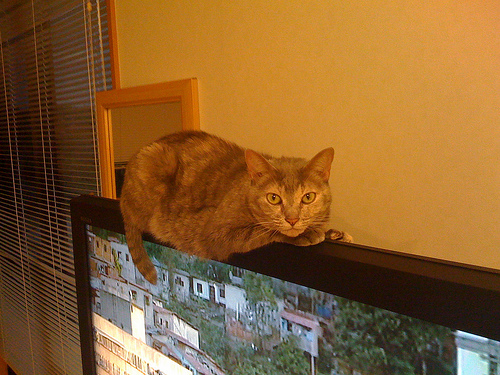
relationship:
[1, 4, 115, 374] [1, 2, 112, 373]
blinds over window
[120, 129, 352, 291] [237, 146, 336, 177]
cat has ears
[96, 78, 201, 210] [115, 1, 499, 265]
mirror on wall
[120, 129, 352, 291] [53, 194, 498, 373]
cat on television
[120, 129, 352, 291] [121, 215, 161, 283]
cat has tail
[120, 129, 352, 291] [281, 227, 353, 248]
cat has paws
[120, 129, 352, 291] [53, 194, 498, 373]
cat on tv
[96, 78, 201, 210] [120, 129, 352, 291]
mirror near cat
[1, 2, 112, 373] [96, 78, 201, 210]
window near mirror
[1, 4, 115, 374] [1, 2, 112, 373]
blinds on window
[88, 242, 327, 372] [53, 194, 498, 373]
houses on television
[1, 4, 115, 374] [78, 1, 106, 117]
blinds have pull string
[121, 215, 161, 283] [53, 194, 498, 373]
tail over television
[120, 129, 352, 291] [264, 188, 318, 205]
cat has eye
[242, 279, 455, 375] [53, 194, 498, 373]
tree on television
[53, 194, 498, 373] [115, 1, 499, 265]
television against wall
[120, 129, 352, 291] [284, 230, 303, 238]
cat has chin